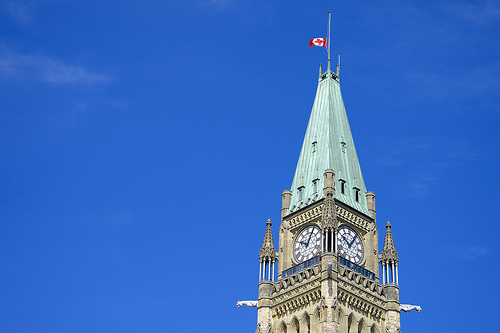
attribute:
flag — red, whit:
[293, 28, 337, 58]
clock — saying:
[288, 222, 326, 264]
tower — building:
[234, 53, 423, 332]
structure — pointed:
[219, 79, 399, 330]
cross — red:
[314, 38, 323, 44]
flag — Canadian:
[305, 33, 328, 49]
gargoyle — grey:
[387, 291, 431, 321]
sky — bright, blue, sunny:
[75, 65, 174, 257]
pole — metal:
[312, 8, 334, 68]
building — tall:
[248, 52, 403, 330]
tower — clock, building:
[241, 91, 412, 315]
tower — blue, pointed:
[280, 58, 386, 325]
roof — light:
[307, 66, 364, 196]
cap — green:
[289, 76, 371, 214]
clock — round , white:
[279, 211, 329, 270]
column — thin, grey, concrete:
[379, 220, 401, 332]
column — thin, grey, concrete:
[258, 215, 276, 331]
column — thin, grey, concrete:
[322, 190, 339, 331]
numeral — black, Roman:
[308, 220, 317, 230]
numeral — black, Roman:
[313, 230, 323, 237]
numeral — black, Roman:
[316, 232, 323, 240]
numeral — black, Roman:
[316, 240, 324, 250]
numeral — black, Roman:
[312, 249, 316, 258]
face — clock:
[293, 224, 323, 261]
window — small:
[346, 310, 355, 330]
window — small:
[355, 315, 367, 331]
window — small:
[369, 320, 378, 331]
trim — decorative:
[270, 264, 322, 315]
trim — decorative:
[339, 262, 390, 319]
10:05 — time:
[294, 226, 320, 247]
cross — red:
[311, 34, 328, 47]